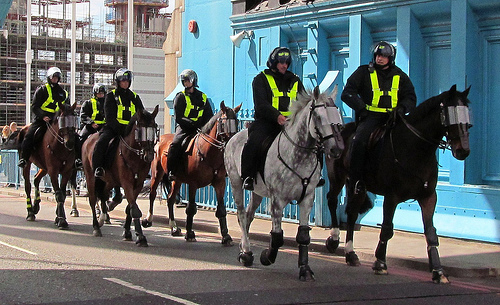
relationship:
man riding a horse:
[239, 47, 309, 191] [214, 87, 354, 275]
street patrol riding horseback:
[18, 41, 420, 196] [13, 83, 472, 282]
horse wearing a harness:
[222, 82, 349, 284] [271, 90, 343, 220]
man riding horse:
[164, 71, 216, 201] [156, 102, 257, 177]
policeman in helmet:
[339, 46, 419, 173] [368, 35, 392, 67]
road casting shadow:
[0, 188, 496, 302] [1, 210, 498, 303]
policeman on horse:
[339, 46, 419, 173] [331, 83, 474, 288]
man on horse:
[164, 71, 216, 201] [148, 97, 242, 246]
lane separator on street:
[0, 241, 200, 302] [3, 209, 196, 303]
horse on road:
[331, 83, 474, 288] [0, 188, 496, 302]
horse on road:
[140, 98, 245, 240] [0, 188, 496, 302]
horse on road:
[75, 103, 165, 239] [0, 188, 496, 302]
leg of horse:
[371, 197, 401, 275] [331, 83, 474, 288]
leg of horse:
[296, 192, 313, 283] [222, 82, 349, 284]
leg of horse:
[262, 192, 296, 269] [222, 82, 349, 284]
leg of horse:
[225, 176, 260, 267] [222, 82, 349, 284]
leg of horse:
[239, 189, 267, 240] [222, 82, 349, 284]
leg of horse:
[186, 185, 198, 242] [153, 103, 243, 242]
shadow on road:
[1, 210, 498, 303] [0, 188, 496, 302]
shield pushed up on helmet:
[115, 68, 133, 78] [107, 66, 135, 86]